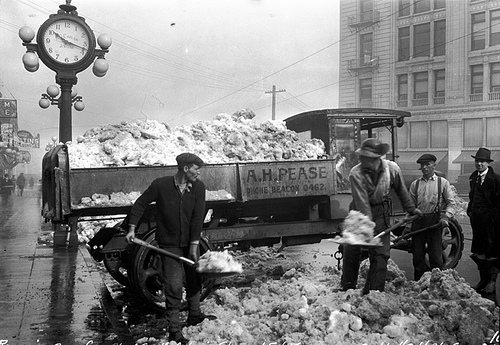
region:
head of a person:
[168, 135, 204, 190]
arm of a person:
[126, 170, 160, 231]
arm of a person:
[180, 210, 208, 258]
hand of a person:
[120, 222, 142, 242]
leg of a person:
[168, 273, 185, 330]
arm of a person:
[358, 176, 376, 221]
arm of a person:
[380, 160, 428, 213]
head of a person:
[355, 124, 388, 171]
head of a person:
[411, 145, 443, 176]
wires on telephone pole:
[16, 4, 302, 112]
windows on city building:
[340, 2, 495, 112]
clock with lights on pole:
[18, 5, 112, 137]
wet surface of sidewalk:
[5, 187, 130, 344]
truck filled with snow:
[42, 106, 458, 297]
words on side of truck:
[240, 160, 327, 197]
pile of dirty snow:
[66, 105, 313, 165]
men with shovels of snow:
[125, 140, 405, 330]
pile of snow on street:
[149, 264, 489, 343]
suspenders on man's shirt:
[410, 174, 447, 213]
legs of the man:
[146, 274, 215, 323]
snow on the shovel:
[196, 235, 251, 282]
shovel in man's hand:
[126, 232, 189, 271]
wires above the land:
[130, 24, 265, 119]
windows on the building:
[381, 46, 488, 115]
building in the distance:
[308, 57, 468, 137]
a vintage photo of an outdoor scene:
[1, 0, 495, 340]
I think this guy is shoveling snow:
[118, 143, 247, 343]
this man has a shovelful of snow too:
[314, 135, 426, 297]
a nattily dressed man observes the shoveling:
[459, 143, 498, 293]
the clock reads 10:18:
[32, 11, 102, 78]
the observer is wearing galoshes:
[466, 248, 498, 297]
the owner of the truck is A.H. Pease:
[241, 157, 333, 200]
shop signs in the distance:
[1, 95, 47, 198]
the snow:
[234, 288, 322, 336]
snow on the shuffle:
[191, 251, 238, 275]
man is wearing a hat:
[175, 154, 200, 165]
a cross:
[268, 86, 282, 116]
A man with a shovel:
[95, 116, 266, 337]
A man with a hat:
[352, 132, 409, 276]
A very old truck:
[8, 86, 442, 257]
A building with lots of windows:
[315, 13, 486, 123]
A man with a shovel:
[276, 145, 426, 285]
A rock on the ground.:
[346, 317, 358, 326]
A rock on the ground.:
[327, 309, 339, 328]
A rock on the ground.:
[293, 304, 310, 318]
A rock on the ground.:
[229, 298, 265, 319]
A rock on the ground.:
[278, 312, 298, 322]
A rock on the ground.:
[261, 315, 308, 333]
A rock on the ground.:
[373, 312, 409, 327]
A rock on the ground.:
[378, 286, 410, 311]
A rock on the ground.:
[343, 295, 383, 325]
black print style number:
[61, 19, 72, 31]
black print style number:
[72, 23, 80, 30]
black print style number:
[83, 38, 89, 51]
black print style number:
[71, 53, 81, 63]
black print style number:
[63, 55, 70, 64]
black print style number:
[53, 52, 60, 62]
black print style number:
[47, 43, 55, 54]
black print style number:
[319, 180, 328, 191]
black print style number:
[301, 180, 308, 191]